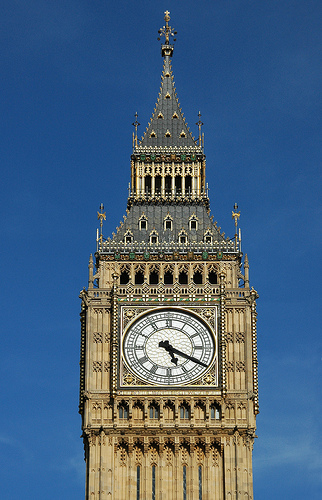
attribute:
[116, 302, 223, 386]
clock — white, round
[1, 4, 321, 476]
sky — blue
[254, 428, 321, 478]
cloud — white